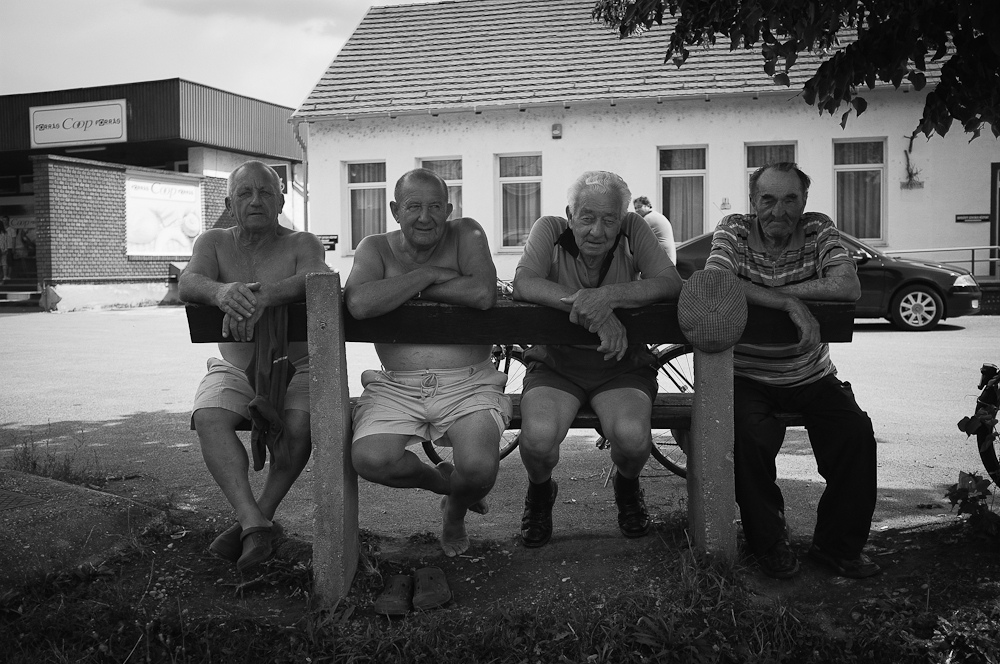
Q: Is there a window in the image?
A: Yes, there is a window.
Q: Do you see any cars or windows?
A: Yes, there is a window.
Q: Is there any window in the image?
A: Yes, there is a window.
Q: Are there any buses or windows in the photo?
A: Yes, there is a window.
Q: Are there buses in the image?
A: No, there are no buses.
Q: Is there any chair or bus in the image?
A: No, there are no buses or chairs.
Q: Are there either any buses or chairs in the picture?
A: No, there are no buses or chairs.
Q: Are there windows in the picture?
A: Yes, there is a window.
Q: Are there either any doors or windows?
A: Yes, there is a window.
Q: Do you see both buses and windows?
A: No, there is a window but no buses.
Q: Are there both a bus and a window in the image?
A: No, there is a window but no buses.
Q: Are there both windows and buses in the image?
A: No, there is a window but no buses.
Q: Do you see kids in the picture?
A: No, there are no kids.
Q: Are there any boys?
A: No, there are no boys.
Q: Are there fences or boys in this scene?
A: No, there are no boys or fences.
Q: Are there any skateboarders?
A: No, there are no skateboarders.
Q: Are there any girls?
A: No, there are no girls.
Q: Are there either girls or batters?
A: No, there are no girls or batters.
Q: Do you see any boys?
A: No, there are no boys.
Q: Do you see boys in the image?
A: No, there are no boys.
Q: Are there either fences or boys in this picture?
A: No, there are no boys or fences.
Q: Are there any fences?
A: No, there are no fences.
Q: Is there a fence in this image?
A: No, there are no fences.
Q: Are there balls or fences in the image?
A: No, there are no fences or balls.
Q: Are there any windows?
A: Yes, there is a window.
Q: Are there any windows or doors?
A: Yes, there is a window.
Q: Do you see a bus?
A: No, there are no buses.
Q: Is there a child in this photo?
A: No, there are no children.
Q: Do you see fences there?
A: No, there are no fences.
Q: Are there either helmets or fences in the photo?
A: No, there are no fences or helmets.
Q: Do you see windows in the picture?
A: Yes, there is a window.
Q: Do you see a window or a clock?
A: Yes, there is a window.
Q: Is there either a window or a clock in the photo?
A: Yes, there is a window.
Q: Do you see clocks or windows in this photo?
A: Yes, there is a window.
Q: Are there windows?
A: Yes, there is a window.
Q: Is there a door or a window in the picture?
A: Yes, there is a window.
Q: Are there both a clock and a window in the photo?
A: No, there is a window but no clocks.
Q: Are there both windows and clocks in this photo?
A: No, there is a window but no clocks.